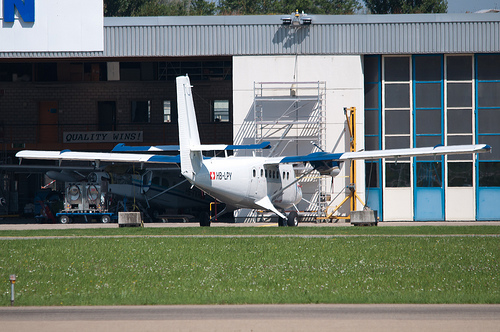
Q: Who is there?
A: No one.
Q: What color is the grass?
A: Green.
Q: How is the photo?
A: Clear.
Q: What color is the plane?
A: White.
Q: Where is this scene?
A: Airport.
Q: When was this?
A: Daytime.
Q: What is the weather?
A: Sunny.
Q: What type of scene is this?
A: Outdoor.